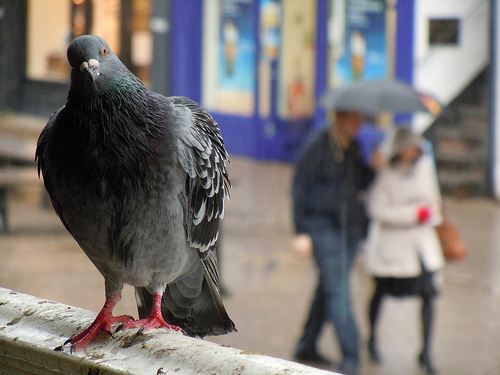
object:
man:
[291, 104, 383, 375]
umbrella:
[322, 80, 429, 117]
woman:
[361, 127, 444, 375]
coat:
[362, 155, 445, 278]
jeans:
[300, 218, 358, 355]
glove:
[418, 206, 428, 222]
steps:
[424, 68, 494, 197]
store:
[0, 0, 496, 162]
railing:
[0, 288, 342, 375]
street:
[0, 111, 500, 375]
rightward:
[464, 196, 499, 374]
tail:
[135, 259, 238, 340]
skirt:
[373, 271, 437, 297]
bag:
[435, 221, 467, 259]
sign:
[218, 0, 257, 91]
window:
[256, 0, 317, 121]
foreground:
[35, 34, 238, 354]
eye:
[102, 46, 107, 55]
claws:
[64, 292, 135, 354]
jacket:
[292, 126, 375, 234]